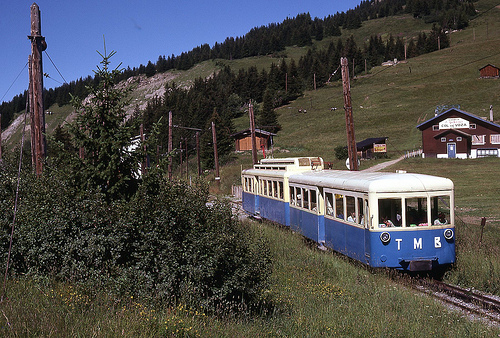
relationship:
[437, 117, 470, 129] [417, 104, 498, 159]
banner on building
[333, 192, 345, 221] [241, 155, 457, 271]
window on train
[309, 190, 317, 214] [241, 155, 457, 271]
window on train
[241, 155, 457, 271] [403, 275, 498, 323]
train on tracks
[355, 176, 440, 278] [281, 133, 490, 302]
window on a train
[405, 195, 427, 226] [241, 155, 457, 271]
window on train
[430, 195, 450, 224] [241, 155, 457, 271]
window on train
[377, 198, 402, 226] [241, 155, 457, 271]
window on train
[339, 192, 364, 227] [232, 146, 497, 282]
window on train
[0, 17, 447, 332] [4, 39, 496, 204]
trees on hill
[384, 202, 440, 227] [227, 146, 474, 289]
people on train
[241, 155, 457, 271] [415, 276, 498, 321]
train on track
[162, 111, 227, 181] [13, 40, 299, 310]
post behind bushes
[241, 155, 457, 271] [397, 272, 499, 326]
train on tracks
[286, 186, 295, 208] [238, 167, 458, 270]
window on train